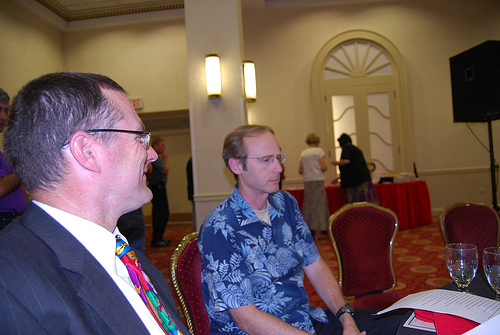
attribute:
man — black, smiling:
[0, 70, 197, 332]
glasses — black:
[59, 127, 150, 149]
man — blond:
[199, 122, 369, 332]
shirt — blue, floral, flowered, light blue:
[196, 187, 327, 333]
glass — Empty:
[447, 242, 477, 292]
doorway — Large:
[304, 15, 422, 209]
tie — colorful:
[117, 230, 193, 333]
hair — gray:
[11, 66, 125, 196]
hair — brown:
[217, 111, 280, 174]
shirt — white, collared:
[33, 195, 174, 333]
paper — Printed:
[400, 308, 432, 333]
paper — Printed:
[373, 286, 498, 320]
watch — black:
[331, 300, 358, 320]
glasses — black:
[80, 117, 152, 149]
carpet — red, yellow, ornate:
[124, 215, 494, 329]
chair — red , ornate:
[324, 190, 414, 317]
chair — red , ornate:
[437, 186, 497, 286]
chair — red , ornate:
[167, 219, 216, 333]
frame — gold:
[169, 222, 207, 332]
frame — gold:
[326, 195, 402, 293]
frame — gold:
[437, 195, 495, 276]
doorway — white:
[302, 24, 418, 198]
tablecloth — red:
[284, 171, 436, 231]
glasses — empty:
[482, 244, 498, 298]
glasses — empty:
[444, 240, 482, 294]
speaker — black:
[447, 28, 497, 222]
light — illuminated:
[202, 50, 225, 102]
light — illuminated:
[240, 55, 261, 111]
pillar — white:
[180, 0, 254, 230]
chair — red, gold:
[431, 193, 498, 285]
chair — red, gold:
[326, 190, 407, 302]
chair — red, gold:
[171, 222, 211, 332]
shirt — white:
[297, 140, 333, 185]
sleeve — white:
[317, 146, 331, 164]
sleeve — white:
[295, 148, 309, 166]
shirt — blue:
[195, 177, 325, 329]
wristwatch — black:
[338, 295, 363, 325]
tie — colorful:
[109, 230, 183, 333]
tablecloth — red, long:
[260, 171, 438, 227]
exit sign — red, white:
[125, 96, 145, 111]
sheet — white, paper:
[383, 285, 497, 327]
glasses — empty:
[443, 243, 498, 296]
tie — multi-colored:
[111, 233, 196, 333]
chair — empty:
[312, 201, 402, 327]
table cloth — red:
[382, 183, 427, 228]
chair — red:
[328, 204, 420, 322]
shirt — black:
[334, 141, 369, 172]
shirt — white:
[295, 142, 329, 187]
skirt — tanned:
[299, 179, 329, 236]